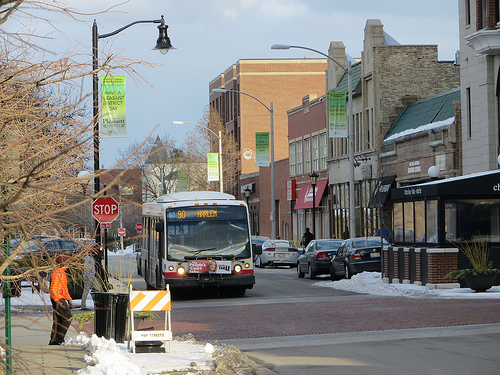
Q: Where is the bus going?
A: Harlem.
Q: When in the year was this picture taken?
A: Winter.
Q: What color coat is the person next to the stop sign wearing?
A: Orange.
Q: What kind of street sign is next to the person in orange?
A: Stop.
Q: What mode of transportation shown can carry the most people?
A: Bus.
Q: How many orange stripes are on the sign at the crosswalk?
A: 3.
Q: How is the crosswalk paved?
A: Brick.